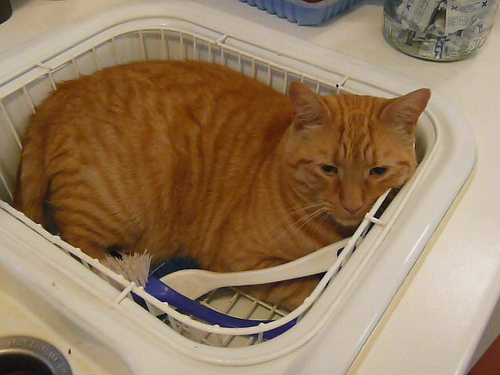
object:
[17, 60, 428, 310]
cat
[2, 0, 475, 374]
sink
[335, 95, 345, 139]
stripe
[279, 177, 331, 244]
stripe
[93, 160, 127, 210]
stripe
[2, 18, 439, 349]
sink rack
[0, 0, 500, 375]
counter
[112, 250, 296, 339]
dish scrubber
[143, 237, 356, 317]
dish scrubber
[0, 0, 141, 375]
left side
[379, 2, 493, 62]
jar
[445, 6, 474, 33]
inscrutable papers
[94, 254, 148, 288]
bristles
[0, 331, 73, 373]
drain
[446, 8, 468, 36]
wipe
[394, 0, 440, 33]
wipe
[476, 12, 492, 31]
wipe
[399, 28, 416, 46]
wipe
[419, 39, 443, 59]
wipe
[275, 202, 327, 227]
whiskers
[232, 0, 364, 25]
container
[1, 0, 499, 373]
counter top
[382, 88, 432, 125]
ear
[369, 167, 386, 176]
eye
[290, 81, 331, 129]
ear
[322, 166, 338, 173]
eye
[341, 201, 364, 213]
nose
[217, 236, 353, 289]
long handle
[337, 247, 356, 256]
end hole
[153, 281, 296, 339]
long handle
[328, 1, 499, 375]
right side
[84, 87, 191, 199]
fur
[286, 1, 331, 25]
edge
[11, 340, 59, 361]
writing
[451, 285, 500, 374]
edge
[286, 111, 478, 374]
fluted edges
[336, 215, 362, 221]
mouth